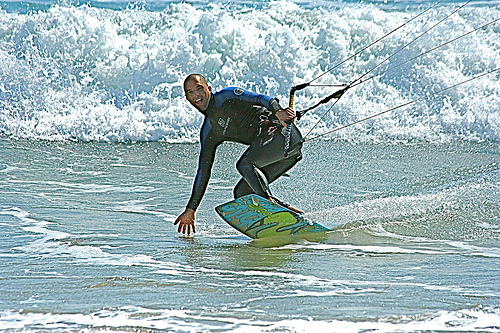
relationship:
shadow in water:
[166, 233, 326, 286] [5, 5, 495, 328]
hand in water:
[174, 211, 196, 234] [5, 5, 495, 328]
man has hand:
[174, 74, 301, 232] [174, 211, 196, 234]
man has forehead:
[174, 74, 301, 232] [182, 76, 202, 93]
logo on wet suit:
[229, 88, 247, 101] [183, 85, 307, 210]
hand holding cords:
[272, 103, 295, 130] [277, 4, 482, 168]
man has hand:
[174, 74, 301, 232] [272, 103, 295, 130]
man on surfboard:
[174, 74, 301, 232] [211, 192, 335, 244]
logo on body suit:
[213, 113, 233, 143] [179, 84, 311, 220]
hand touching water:
[174, 211, 196, 234] [5, 5, 495, 328]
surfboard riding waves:
[218, 194, 322, 254] [277, 167, 498, 267]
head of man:
[180, 71, 220, 121] [174, 74, 301, 232]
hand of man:
[170, 205, 203, 240] [174, 74, 301, 232]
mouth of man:
[194, 99, 206, 106] [174, 74, 301, 232]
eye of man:
[194, 83, 206, 93] [174, 74, 301, 232]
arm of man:
[168, 135, 218, 234] [174, 74, 301, 232]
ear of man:
[202, 78, 213, 96] [174, 74, 301, 232]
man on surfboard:
[150, 65, 316, 241] [210, 182, 322, 261]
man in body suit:
[174, 74, 301, 232] [187, 87, 304, 209]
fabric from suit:
[213, 85, 282, 108] [184, 86, 314, 215]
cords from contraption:
[349, 16, 499, 88] [270, 5, 499, 175]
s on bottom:
[252, 210, 319, 250] [215, 193, 322, 245]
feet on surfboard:
[234, 192, 303, 221] [215, 194, 332, 240]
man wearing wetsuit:
[174, 74, 301, 232] [184, 88, 313, 218]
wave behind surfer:
[4, 3, 494, 156] [150, 63, 322, 235]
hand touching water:
[275, 108, 294, 127] [5, 5, 495, 328]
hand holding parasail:
[275, 108, 294, 127] [282, 1, 482, 160]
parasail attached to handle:
[282, 1, 482, 160] [282, 85, 296, 154]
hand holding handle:
[275, 108, 294, 127] [282, 85, 296, 154]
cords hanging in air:
[349, 16, 499, 88] [1, 1, 484, 327]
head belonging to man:
[184, 73, 212, 110] [172, 70, 306, 235]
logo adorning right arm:
[234, 88, 244, 95] [223, 84, 282, 113]